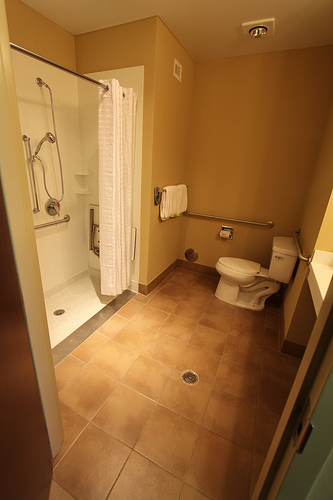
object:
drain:
[180, 368, 200, 386]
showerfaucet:
[34, 101, 58, 162]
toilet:
[210, 255, 268, 306]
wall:
[210, 82, 298, 222]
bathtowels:
[162, 184, 180, 220]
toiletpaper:
[221, 231, 229, 240]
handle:
[183, 207, 273, 228]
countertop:
[314, 264, 331, 306]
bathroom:
[4, 6, 332, 338]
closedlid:
[220, 254, 261, 275]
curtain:
[99, 82, 144, 297]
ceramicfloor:
[44, 258, 307, 500]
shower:
[18, 48, 121, 329]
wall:
[158, 102, 198, 294]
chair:
[87, 204, 99, 256]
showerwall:
[79, 133, 143, 295]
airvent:
[173, 59, 183, 82]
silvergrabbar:
[289, 228, 309, 264]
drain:
[53, 308, 65, 315]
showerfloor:
[36, 262, 126, 341]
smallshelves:
[73, 170, 90, 176]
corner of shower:
[75, 97, 96, 225]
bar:
[160, 184, 189, 193]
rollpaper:
[220, 229, 232, 239]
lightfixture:
[241, 18, 275, 38]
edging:
[249, 26, 269, 38]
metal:
[34, 134, 55, 153]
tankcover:
[272, 231, 298, 256]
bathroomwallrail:
[31, 214, 70, 230]